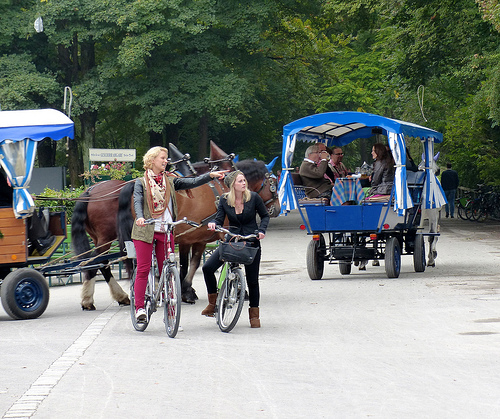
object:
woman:
[201, 170, 271, 329]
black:
[228, 221, 240, 228]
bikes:
[129, 216, 200, 338]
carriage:
[289, 170, 424, 233]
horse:
[72, 159, 281, 310]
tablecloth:
[330, 177, 365, 205]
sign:
[90, 148, 136, 162]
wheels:
[306, 239, 325, 281]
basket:
[217, 239, 254, 263]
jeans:
[203, 242, 261, 306]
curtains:
[277, 124, 298, 216]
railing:
[455, 186, 497, 216]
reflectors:
[299, 225, 306, 231]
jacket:
[130, 173, 212, 227]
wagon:
[300, 198, 428, 280]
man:
[299, 142, 336, 199]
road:
[0, 208, 500, 419]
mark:
[471, 297, 485, 300]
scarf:
[144, 169, 177, 219]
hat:
[314, 143, 326, 147]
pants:
[135, 231, 176, 315]